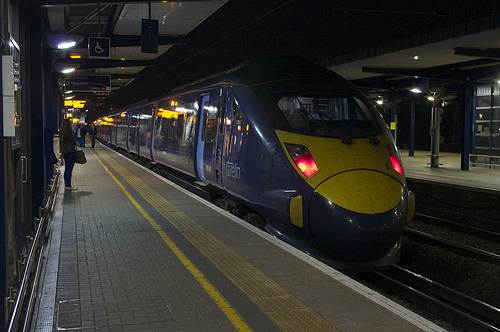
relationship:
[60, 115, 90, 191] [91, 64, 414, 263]
woman waiting for train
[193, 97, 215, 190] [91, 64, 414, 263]
side door for entering on train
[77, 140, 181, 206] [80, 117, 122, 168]
sidewalk area is where people cross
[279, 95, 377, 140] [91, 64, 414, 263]
front windshield of train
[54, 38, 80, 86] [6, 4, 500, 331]
lights illuminate station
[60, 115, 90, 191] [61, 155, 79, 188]
woman wearing jeans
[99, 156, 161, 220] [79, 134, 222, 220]
yellow stripes on sidewalk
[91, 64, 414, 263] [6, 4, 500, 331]
train at station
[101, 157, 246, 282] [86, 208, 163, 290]
yellow lines on pavement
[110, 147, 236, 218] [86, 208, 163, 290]
white line on pavement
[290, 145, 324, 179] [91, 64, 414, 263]
headlight on right front of train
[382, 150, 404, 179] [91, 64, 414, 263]
headlight on left front of train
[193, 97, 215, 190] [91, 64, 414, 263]
door area on train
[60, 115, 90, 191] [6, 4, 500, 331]
woman standing at station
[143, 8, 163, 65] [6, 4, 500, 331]
sign seen at station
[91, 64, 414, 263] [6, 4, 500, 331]
train in station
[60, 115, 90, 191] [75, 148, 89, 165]
woman holding purse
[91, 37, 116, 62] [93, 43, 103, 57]
sign has wheelchair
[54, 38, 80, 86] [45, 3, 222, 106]
lights in ceiling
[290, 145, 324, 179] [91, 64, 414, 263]
headlight lit on train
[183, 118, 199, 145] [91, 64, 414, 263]
man inside train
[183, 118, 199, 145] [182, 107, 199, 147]
conductor behind window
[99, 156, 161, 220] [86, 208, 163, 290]
yellow line on pavement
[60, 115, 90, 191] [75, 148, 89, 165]
she carrying brown bag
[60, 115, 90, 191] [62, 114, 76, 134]
she has brown hair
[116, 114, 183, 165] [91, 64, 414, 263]
reflection on train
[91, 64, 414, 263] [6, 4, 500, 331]
subway at station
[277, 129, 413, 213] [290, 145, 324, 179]
front has headlight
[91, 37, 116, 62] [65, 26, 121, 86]
sign for handicapped area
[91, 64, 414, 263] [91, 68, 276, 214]
train mostly blue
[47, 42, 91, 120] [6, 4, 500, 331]
overhead lights in station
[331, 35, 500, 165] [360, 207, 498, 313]
opposite side of track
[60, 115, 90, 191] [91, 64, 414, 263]
person waiting for train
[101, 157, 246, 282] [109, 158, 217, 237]
yellow lines for safety